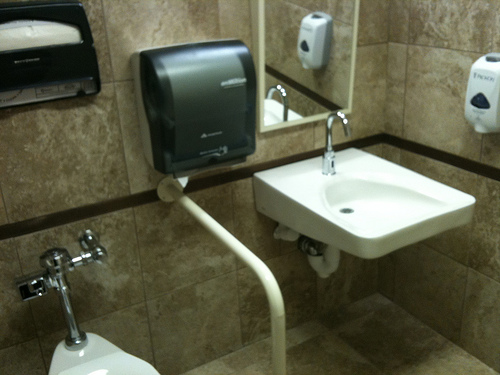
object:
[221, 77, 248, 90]
writing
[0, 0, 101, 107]
container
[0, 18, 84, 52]
cover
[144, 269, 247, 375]
tile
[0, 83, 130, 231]
tile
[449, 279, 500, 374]
tile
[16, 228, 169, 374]
toilet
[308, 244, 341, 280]
pipe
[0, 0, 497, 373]
wall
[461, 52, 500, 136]
container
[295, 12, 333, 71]
soap dispenser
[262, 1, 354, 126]
mirror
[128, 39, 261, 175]
container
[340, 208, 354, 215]
drain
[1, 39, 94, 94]
toiler seat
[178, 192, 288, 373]
bar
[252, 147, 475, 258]
sink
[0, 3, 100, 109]
dispenser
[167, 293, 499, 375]
floor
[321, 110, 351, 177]
faucet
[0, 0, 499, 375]
scene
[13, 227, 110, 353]
plumbing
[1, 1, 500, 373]
bathroom wall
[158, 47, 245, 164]
towel